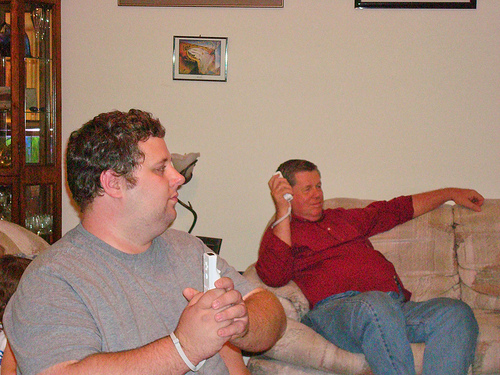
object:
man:
[0, 106, 288, 375]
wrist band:
[168, 332, 206, 372]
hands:
[176, 287, 235, 360]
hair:
[273, 158, 321, 187]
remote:
[267, 170, 292, 230]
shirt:
[2, 224, 259, 375]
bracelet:
[164, 328, 206, 372]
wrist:
[163, 330, 210, 373]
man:
[252, 157, 485, 375]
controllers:
[199, 250, 223, 295]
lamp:
[169, 151, 203, 233]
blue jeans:
[304, 285, 479, 373]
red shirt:
[254, 194, 415, 305]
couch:
[242, 196, 500, 374]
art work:
[170, 33, 230, 82]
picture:
[168, 32, 231, 84]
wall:
[61, 0, 498, 272]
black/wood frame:
[351, 0, 479, 12]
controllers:
[269, 170, 295, 202]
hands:
[181, 275, 249, 342]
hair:
[64, 107, 167, 211]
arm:
[330, 185, 483, 245]